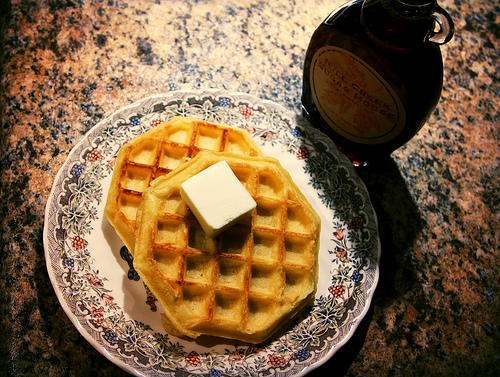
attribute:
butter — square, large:
[179, 160, 257, 239]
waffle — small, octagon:
[132, 147, 319, 344]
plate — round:
[41, 89, 380, 376]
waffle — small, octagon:
[106, 114, 264, 258]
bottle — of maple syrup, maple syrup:
[289, 0, 464, 164]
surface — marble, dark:
[1, 1, 499, 376]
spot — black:
[136, 38, 154, 56]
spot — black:
[224, 6, 239, 17]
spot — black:
[241, 42, 254, 58]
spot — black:
[213, 63, 226, 74]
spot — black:
[93, 33, 106, 49]